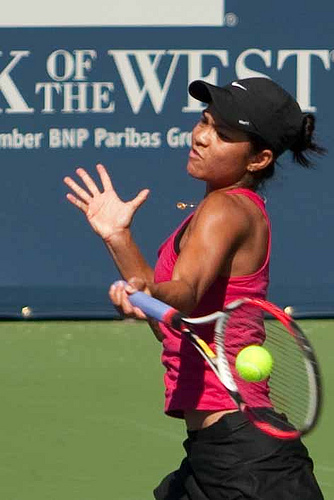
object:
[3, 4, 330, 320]
banner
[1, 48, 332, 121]
bank of west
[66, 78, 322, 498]
woman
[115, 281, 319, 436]
racquet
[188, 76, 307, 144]
cap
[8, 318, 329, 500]
court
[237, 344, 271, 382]
ball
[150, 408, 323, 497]
skort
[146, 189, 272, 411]
shirt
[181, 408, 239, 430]
stomach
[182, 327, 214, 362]
racket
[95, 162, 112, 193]
finger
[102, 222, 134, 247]
wrist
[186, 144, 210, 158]
mouth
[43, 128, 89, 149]
bnp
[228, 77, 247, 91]
nike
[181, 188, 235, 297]
muscle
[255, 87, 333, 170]
hairdo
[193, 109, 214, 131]
eyes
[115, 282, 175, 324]
grip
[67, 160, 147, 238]
palm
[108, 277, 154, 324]
hand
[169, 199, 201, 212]
pendant